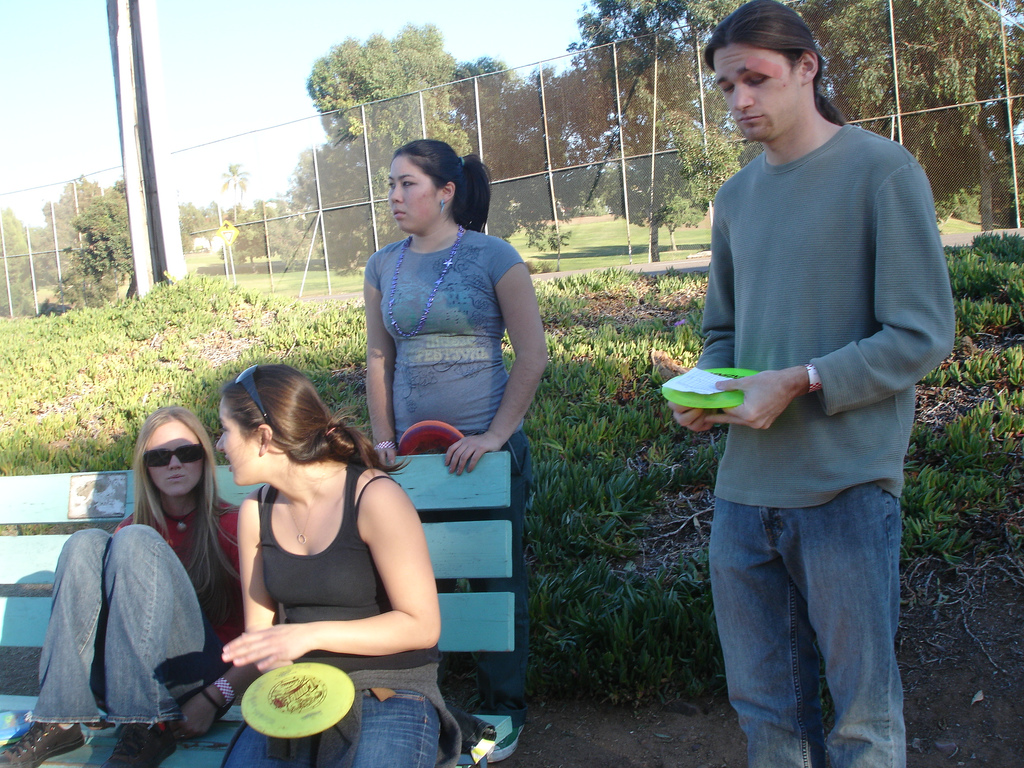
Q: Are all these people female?
A: No, they are both male and female.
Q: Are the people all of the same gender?
A: No, they are both male and female.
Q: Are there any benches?
A: Yes, there is a bench.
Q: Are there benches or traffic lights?
A: Yes, there is a bench.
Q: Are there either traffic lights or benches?
A: Yes, there is a bench.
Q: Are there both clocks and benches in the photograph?
A: No, there is a bench but no clocks.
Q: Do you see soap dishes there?
A: No, there are no soap dishes.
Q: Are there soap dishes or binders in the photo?
A: No, there are no soap dishes or binders.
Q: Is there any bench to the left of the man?
A: Yes, there is a bench to the left of the man.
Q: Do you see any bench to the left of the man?
A: Yes, there is a bench to the left of the man.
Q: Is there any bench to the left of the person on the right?
A: Yes, there is a bench to the left of the man.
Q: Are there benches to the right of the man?
A: No, the bench is to the left of the man.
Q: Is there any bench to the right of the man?
A: No, the bench is to the left of the man.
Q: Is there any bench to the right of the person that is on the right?
A: No, the bench is to the left of the man.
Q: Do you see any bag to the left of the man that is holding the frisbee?
A: No, there is a bench to the left of the man.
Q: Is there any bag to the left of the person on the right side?
A: No, there is a bench to the left of the man.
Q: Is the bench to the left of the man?
A: Yes, the bench is to the left of the man.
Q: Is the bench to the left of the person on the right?
A: Yes, the bench is to the left of the man.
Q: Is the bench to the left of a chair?
A: No, the bench is to the left of the man.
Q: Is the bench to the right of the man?
A: No, the bench is to the left of the man.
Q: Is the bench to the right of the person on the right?
A: No, the bench is to the left of the man.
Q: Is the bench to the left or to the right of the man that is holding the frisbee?
A: The bench is to the left of the man.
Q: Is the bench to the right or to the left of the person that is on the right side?
A: The bench is to the left of the man.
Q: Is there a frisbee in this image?
A: Yes, there is a frisbee.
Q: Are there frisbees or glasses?
A: Yes, there is a frisbee.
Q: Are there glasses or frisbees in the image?
A: Yes, there is a frisbee.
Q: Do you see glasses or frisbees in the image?
A: Yes, there is a frisbee.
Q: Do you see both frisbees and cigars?
A: No, there is a frisbee but no cigars.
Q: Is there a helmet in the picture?
A: No, there are no helmets.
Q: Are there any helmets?
A: No, there are no helmets.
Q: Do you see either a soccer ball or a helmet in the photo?
A: No, there are no helmets or soccer balls.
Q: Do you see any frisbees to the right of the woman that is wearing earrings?
A: Yes, there is a frisbee to the right of the woman.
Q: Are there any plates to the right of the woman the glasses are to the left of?
A: No, there is a frisbee to the right of the woman.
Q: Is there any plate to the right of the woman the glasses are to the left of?
A: No, there is a frisbee to the right of the woman.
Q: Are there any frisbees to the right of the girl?
A: Yes, there is a frisbee to the right of the girl.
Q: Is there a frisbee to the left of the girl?
A: No, the frisbee is to the right of the girl.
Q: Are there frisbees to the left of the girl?
A: No, the frisbee is to the right of the girl.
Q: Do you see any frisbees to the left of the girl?
A: No, the frisbee is to the right of the girl.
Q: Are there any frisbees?
A: Yes, there is a frisbee.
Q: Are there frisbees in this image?
A: Yes, there is a frisbee.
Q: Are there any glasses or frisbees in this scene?
A: Yes, there is a frisbee.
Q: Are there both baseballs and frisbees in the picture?
A: No, there is a frisbee but no baseballs.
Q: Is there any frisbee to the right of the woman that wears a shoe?
A: Yes, there is a frisbee to the right of the woman.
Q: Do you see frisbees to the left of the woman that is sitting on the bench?
A: No, the frisbee is to the right of the woman.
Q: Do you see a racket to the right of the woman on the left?
A: No, there is a frisbee to the right of the woman.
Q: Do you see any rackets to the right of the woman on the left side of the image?
A: No, there is a frisbee to the right of the woman.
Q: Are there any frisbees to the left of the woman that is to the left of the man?
A: Yes, there is a frisbee to the left of the woman.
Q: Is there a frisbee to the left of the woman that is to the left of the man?
A: Yes, there is a frisbee to the left of the woman.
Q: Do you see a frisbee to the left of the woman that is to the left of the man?
A: Yes, there is a frisbee to the left of the woman.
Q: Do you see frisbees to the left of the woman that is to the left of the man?
A: Yes, there is a frisbee to the left of the woman.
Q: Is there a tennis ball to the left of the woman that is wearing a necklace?
A: No, there is a frisbee to the left of the woman.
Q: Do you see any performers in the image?
A: No, there are no performers.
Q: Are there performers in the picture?
A: No, there are no performers.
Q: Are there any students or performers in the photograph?
A: No, there are no performers or students.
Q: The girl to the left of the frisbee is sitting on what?
A: The girl is sitting on the bench.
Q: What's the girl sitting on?
A: The girl is sitting on the bench.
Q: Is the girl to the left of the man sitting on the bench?
A: Yes, the girl is sitting on the bench.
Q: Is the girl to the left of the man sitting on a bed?
A: No, the girl is sitting on the bench.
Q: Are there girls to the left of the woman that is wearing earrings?
A: Yes, there is a girl to the left of the woman.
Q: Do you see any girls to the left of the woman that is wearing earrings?
A: Yes, there is a girl to the left of the woman.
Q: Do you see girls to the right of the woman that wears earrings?
A: No, the girl is to the left of the woman.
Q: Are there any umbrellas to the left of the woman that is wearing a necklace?
A: No, there is a girl to the left of the woman.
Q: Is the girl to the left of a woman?
A: Yes, the girl is to the left of a woman.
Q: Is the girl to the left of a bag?
A: No, the girl is to the left of a woman.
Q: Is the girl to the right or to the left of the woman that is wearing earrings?
A: The girl is to the left of the woman.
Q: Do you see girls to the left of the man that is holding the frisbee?
A: Yes, there is a girl to the left of the man.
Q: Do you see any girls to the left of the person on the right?
A: Yes, there is a girl to the left of the man.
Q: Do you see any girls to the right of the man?
A: No, the girl is to the left of the man.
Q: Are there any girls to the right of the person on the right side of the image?
A: No, the girl is to the left of the man.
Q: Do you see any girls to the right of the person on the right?
A: No, the girl is to the left of the man.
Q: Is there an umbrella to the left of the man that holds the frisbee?
A: No, there is a girl to the left of the man.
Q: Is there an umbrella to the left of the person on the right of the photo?
A: No, there is a girl to the left of the man.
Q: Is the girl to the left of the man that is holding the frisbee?
A: Yes, the girl is to the left of the man.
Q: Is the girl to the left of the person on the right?
A: Yes, the girl is to the left of the man.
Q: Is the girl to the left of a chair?
A: No, the girl is to the left of the man.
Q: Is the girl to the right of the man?
A: No, the girl is to the left of the man.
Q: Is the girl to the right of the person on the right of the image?
A: No, the girl is to the left of the man.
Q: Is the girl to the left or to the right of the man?
A: The girl is to the left of the man.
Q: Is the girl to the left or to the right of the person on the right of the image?
A: The girl is to the left of the man.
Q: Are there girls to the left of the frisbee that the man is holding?
A: Yes, there is a girl to the left of the frisbee.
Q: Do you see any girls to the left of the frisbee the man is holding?
A: Yes, there is a girl to the left of the frisbee.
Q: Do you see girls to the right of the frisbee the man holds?
A: No, the girl is to the left of the frisbee.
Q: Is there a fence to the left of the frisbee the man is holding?
A: No, there is a girl to the left of the frisbee.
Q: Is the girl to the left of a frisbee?
A: Yes, the girl is to the left of a frisbee.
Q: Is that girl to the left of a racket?
A: No, the girl is to the left of a frisbee.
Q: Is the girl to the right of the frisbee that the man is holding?
A: No, the girl is to the left of the frisbee.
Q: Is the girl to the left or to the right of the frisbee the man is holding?
A: The girl is to the left of the frisbee.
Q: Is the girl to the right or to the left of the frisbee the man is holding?
A: The girl is to the left of the frisbee.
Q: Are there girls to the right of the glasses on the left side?
A: Yes, there is a girl to the right of the glasses.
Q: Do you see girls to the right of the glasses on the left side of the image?
A: Yes, there is a girl to the right of the glasses.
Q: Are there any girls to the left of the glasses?
A: No, the girl is to the right of the glasses.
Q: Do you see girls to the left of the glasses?
A: No, the girl is to the right of the glasses.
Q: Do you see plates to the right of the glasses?
A: No, there is a girl to the right of the glasses.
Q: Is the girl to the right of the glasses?
A: Yes, the girl is to the right of the glasses.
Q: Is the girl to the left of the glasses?
A: No, the girl is to the right of the glasses.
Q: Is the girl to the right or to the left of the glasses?
A: The girl is to the right of the glasses.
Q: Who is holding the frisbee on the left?
A: The girl is holding the frisbee.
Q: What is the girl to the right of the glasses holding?
A: The girl is holding the frisbee.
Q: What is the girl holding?
A: The girl is holding the frisbee.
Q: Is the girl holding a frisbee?
A: Yes, the girl is holding a frisbee.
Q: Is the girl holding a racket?
A: No, the girl is holding a frisbee.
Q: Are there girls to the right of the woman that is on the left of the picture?
A: Yes, there is a girl to the right of the woman.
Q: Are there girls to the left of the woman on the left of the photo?
A: No, the girl is to the right of the woman.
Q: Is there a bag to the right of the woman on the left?
A: No, there is a girl to the right of the woman.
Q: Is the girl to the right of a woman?
A: Yes, the girl is to the right of a woman.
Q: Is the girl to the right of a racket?
A: No, the girl is to the right of a woman.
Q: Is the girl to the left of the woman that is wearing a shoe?
A: No, the girl is to the right of the woman.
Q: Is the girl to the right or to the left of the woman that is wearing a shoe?
A: The girl is to the right of the woman.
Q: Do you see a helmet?
A: No, there are no helmets.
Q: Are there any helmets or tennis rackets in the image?
A: No, there are no helmets or tennis rackets.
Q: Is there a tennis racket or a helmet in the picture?
A: No, there are no helmets or rackets.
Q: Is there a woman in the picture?
A: Yes, there is a woman.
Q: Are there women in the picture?
A: Yes, there is a woman.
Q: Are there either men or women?
A: Yes, there is a woman.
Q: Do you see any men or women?
A: Yes, there is a woman.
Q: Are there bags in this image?
A: No, there are no bags.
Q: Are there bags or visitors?
A: No, there are no bags or visitors.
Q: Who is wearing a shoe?
A: The woman is wearing a shoe.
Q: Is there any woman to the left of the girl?
A: Yes, there is a woman to the left of the girl.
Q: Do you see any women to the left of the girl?
A: Yes, there is a woman to the left of the girl.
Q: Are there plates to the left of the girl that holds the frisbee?
A: No, there is a woman to the left of the girl.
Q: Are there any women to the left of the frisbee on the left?
A: Yes, there is a woman to the left of the frisbee.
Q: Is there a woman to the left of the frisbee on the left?
A: Yes, there is a woman to the left of the frisbee.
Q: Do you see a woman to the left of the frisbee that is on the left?
A: Yes, there is a woman to the left of the frisbee.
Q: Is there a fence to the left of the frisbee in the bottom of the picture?
A: No, there is a woman to the left of the frisbee.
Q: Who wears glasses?
A: The woman wears glasses.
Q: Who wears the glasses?
A: The woman wears glasses.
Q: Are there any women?
A: Yes, there is a woman.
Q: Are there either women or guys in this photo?
A: Yes, there is a woman.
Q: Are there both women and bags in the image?
A: No, there is a woman but no bags.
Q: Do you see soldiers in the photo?
A: No, there are no soldiers.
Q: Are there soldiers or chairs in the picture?
A: No, there are no soldiers or chairs.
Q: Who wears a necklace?
A: The woman wears a necklace.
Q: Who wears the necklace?
A: The woman wears a necklace.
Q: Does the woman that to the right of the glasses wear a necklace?
A: Yes, the woman wears a necklace.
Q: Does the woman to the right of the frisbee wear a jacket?
A: No, the woman wears a necklace.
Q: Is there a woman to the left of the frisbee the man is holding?
A: Yes, there is a woman to the left of the frisbee.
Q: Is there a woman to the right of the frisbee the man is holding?
A: No, the woman is to the left of the frisbee.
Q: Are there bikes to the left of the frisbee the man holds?
A: No, there is a woman to the left of the frisbee.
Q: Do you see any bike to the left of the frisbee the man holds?
A: No, there is a woman to the left of the frisbee.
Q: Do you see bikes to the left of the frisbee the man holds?
A: No, there is a woman to the left of the frisbee.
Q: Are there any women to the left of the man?
A: Yes, there is a woman to the left of the man.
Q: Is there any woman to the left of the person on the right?
A: Yes, there is a woman to the left of the man.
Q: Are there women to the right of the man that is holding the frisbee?
A: No, the woman is to the left of the man.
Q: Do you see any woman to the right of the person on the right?
A: No, the woman is to the left of the man.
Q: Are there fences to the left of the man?
A: No, there is a woman to the left of the man.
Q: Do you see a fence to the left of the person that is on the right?
A: No, there is a woman to the left of the man.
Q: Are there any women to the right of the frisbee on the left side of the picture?
A: Yes, there is a woman to the right of the frisbee.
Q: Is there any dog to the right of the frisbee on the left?
A: No, there is a woman to the right of the frisbee.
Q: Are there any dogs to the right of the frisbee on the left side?
A: No, there is a woman to the right of the frisbee.